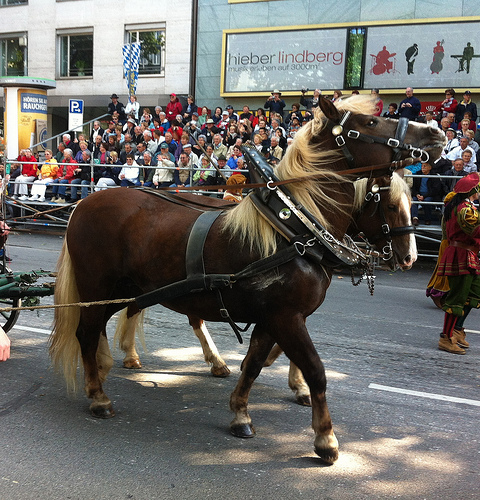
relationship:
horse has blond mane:
[47, 91, 449, 464] [226, 85, 377, 252]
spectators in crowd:
[86, 114, 281, 183] [9, 86, 479, 223]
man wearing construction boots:
[432, 172, 476, 358] [429, 330, 471, 357]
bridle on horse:
[234, 143, 381, 285] [47, 91, 449, 464]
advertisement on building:
[215, 30, 478, 94] [1, 1, 479, 152]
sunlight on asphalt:
[145, 330, 344, 401] [0, 217, 466, 490]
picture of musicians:
[361, 29, 478, 89] [374, 42, 479, 76]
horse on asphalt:
[47, 91, 449, 464] [0, 217, 466, 490]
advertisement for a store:
[215, 30, 478, 94] [182, 12, 479, 212]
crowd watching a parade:
[9, 86, 479, 223] [2, 203, 477, 331]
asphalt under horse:
[0, 217, 466, 490] [47, 91, 449, 464]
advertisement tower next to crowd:
[4, 74, 55, 180] [9, 86, 479, 223]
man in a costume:
[432, 172, 476, 358] [437, 186, 477, 314]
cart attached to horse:
[0, 239, 55, 347] [47, 91, 449, 464]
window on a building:
[51, 21, 101, 79] [1, 1, 479, 152]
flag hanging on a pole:
[117, 45, 148, 81] [120, 30, 147, 129]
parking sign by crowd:
[68, 97, 85, 117] [9, 86, 479, 223]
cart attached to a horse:
[0, 239, 55, 347] [47, 91, 449, 464]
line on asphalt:
[367, 373, 479, 422] [0, 217, 466, 490]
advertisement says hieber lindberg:
[215, 30, 478, 94] [230, 50, 347, 65]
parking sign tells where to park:
[68, 97, 85, 117] [49, 115, 92, 171]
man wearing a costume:
[432, 172, 476, 358] [437, 186, 477, 314]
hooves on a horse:
[223, 425, 367, 472] [47, 91, 449, 464]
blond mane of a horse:
[226, 85, 377, 252] [47, 91, 449, 464]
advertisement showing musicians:
[215, 30, 478, 94] [374, 42, 479, 76]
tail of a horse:
[39, 230, 86, 405] [47, 91, 449, 464]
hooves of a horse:
[223, 425, 367, 472] [47, 91, 449, 464]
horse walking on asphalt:
[47, 91, 449, 464] [0, 217, 466, 490]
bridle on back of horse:
[234, 143, 381, 285] [47, 91, 449, 464]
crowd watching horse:
[9, 86, 479, 223] [47, 91, 449, 464]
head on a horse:
[306, 91, 446, 176] [47, 91, 449, 464]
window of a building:
[51, 21, 101, 79] [1, 1, 479, 152]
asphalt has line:
[0, 217, 466, 490] [367, 373, 479, 422]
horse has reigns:
[47, 91, 449, 464] [28, 176, 342, 316]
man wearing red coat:
[432, 172, 476, 358] [436, 200, 479, 276]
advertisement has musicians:
[215, 30, 478, 94] [374, 42, 479, 76]